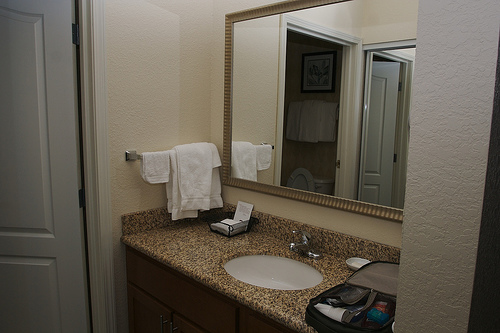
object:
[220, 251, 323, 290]
basin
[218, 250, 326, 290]
sink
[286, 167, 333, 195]
toilet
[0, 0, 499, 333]
photo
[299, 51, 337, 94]
painting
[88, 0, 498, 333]
wall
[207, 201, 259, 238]
basket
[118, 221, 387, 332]
counter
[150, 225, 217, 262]
mosaic slab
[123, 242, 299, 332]
shelves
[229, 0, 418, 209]
reflection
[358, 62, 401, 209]
door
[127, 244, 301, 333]
cabinet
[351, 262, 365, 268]
soap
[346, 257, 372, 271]
soap container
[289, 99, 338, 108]
rack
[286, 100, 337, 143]
towels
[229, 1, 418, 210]
mirror's reflection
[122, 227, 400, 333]
top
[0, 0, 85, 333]
door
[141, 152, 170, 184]
face cloth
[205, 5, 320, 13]
frame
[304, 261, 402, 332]
bag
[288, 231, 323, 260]
faucet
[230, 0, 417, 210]
mirror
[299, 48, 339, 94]
picture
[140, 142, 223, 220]
towel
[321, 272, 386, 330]
toiletries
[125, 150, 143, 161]
rack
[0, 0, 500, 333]
building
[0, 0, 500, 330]
bathroom